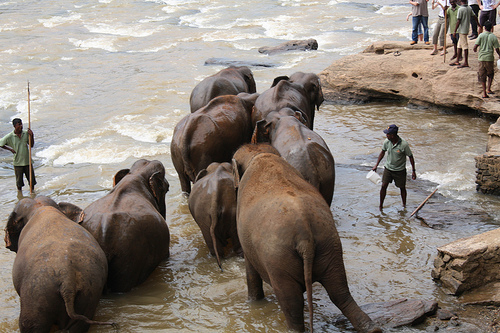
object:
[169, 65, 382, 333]
pack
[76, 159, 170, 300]
elephants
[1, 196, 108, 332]
elephant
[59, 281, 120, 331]
tail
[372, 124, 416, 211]
man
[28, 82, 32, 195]
pole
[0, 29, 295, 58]
waves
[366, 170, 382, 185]
bucket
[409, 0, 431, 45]
people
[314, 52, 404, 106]
shore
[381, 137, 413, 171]
shirt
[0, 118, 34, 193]
person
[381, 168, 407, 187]
shorts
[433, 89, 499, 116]
ledge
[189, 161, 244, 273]
baby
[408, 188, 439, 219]
stick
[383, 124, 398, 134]
blue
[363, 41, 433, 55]
rock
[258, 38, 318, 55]
rock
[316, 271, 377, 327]
leg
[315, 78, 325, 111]
ear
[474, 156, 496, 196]
edge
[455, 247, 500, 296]
wall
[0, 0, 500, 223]
lake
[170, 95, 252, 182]
body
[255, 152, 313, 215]
back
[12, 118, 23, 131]
head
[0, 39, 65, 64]
brown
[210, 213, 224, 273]
skinny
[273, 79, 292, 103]
hump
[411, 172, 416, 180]
hand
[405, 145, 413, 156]
short